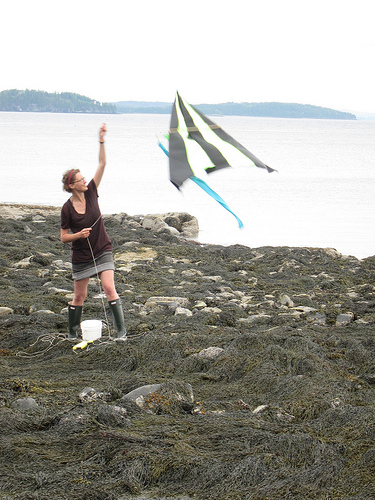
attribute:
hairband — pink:
[62, 166, 80, 192]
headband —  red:
[66, 167, 77, 190]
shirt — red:
[59, 177, 111, 264]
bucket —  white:
[81, 319, 102, 341]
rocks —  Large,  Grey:
[126, 212, 197, 239]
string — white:
[15, 228, 126, 344]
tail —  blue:
[154, 130, 247, 231]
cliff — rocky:
[2, 199, 370, 499]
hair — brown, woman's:
[60, 164, 83, 196]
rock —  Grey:
[121, 382, 193, 413]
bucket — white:
[80, 316, 101, 341]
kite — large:
[161, 88, 282, 182]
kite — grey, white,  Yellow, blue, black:
[152, 87, 288, 235]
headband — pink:
[65, 165, 76, 187]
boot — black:
[108, 297, 128, 342]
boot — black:
[63, 300, 86, 343]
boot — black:
[106, 293, 128, 340]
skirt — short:
[68, 251, 117, 280]